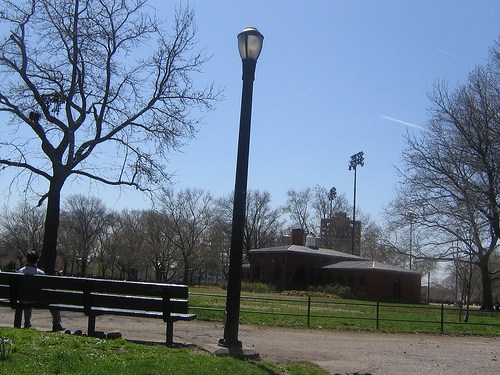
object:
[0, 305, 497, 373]
road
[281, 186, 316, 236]
tree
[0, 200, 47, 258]
tree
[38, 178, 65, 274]
trunk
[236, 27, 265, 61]
lamp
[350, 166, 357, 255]
pole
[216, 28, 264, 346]
lamp post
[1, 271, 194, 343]
bench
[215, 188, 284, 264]
trees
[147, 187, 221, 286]
trees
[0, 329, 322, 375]
grass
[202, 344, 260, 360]
cement block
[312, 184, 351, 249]
trees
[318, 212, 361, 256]
building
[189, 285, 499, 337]
grass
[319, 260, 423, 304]
structure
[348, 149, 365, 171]
flood lights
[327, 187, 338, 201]
flood lights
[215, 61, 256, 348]
light pole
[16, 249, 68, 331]
man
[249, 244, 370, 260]
roof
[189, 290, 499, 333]
fence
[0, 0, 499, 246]
sky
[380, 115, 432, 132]
marking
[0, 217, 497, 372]
park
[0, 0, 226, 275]
tree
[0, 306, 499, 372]
ground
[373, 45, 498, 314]
tree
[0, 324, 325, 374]
area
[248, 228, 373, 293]
building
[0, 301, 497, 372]
walkway